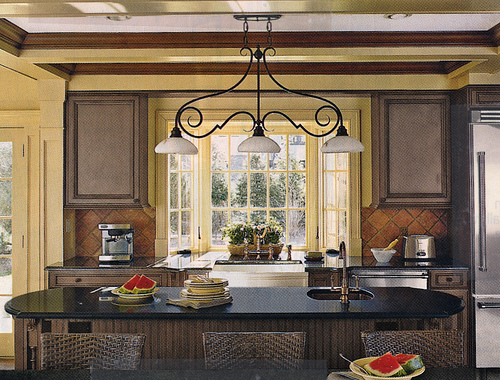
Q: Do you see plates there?
A: Yes, there is a plate.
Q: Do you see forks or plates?
A: Yes, there is a plate.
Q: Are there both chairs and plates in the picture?
A: Yes, there are both a plate and a chair.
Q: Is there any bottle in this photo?
A: No, there are no bottles.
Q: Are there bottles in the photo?
A: No, there are no bottles.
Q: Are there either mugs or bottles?
A: No, there are no bottles or mugs.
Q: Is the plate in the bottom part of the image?
A: Yes, the plate is in the bottom of the image.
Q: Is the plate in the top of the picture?
A: No, the plate is in the bottom of the image.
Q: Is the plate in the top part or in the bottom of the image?
A: The plate is in the bottom of the image.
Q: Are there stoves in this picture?
A: No, there are no stoves.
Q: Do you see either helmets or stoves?
A: No, there are no stoves or helmets.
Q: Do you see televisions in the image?
A: No, there are no televisions.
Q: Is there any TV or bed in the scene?
A: No, there are no televisions or beds.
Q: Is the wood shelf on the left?
A: Yes, the shelf is on the left of the image.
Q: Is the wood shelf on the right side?
A: No, the shelf is on the left of the image.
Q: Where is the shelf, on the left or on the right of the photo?
A: The shelf is on the left of the image.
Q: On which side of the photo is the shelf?
A: The shelf is on the left of the image.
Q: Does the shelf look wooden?
A: Yes, the shelf is wooden.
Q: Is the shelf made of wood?
A: Yes, the shelf is made of wood.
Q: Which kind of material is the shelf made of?
A: The shelf is made of wood.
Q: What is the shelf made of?
A: The shelf is made of wood.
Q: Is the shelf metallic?
A: No, the shelf is wooden.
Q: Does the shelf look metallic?
A: No, the shelf is wooden.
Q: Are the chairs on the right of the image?
A: Yes, the chairs are on the right of the image.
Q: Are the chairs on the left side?
A: No, the chairs are on the right of the image.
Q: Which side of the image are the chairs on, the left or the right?
A: The chairs are on the right of the image.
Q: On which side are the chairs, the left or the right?
A: The chairs are on the right of the image.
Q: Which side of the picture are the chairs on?
A: The chairs are on the right of the image.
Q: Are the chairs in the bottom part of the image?
A: Yes, the chairs are in the bottom of the image.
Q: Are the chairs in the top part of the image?
A: No, the chairs are in the bottom of the image.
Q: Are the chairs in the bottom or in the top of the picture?
A: The chairs are in the bottom of the image.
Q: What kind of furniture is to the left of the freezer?
A: The pieces of furniture are chairs.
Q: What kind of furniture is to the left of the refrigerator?
A: The pieces of furniture are chairs.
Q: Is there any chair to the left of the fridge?
A: Yes, there are chairs to the left of the fridge.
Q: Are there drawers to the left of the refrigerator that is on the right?
A: No, there are chairs to the left of the refrigerator.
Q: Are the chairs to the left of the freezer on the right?
A: Yes, the chairs are to the left of the fridge.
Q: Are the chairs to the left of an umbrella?
A: No, the chairs are to the left of the fridge.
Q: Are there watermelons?
A: Yes, there is a watermelon.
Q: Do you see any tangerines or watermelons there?
A: Yes, there is a watermelon.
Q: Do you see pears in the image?
A: No, there are no pears.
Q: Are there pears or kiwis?
A: No, there are no pears or kiwis.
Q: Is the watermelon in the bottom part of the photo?
A: Yes, the watermelon is in the bottom of the image.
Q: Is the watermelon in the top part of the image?
A: No, the watermelon is in the bottom of the image.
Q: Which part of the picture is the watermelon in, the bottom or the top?
A: The watermelon is in the bottom of the image.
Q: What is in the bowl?
A: The watermelon is in the bowl.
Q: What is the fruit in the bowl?
A: The fruit is a watermelon.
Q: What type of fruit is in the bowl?
A: The fruit is a watermelon.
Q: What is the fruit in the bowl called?
A: The fruit is a watermelon.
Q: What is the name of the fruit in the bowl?
A: The fruit is a watermelon.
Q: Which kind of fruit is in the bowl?
A: The fruit is a watermelon.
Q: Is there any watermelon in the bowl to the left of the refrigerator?
A: Yes, there is a watermelon in the bowl.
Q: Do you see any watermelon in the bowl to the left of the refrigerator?
A: Yes, there is a watermelon in the bowl.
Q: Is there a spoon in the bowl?
A: No, there is a watermelon in the bowl.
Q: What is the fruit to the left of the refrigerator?
A: The fruit is a watermelon.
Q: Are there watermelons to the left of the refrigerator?
A: Yes, there is a watermelon to the left of the refrigerator.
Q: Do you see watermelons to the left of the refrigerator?
A: Yes, there is a watermelon to the left of the refrigerator.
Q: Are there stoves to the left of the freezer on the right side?
A: No, there is a watermelon to the left of the refrigerator.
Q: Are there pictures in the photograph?
A: No, there are no pictures.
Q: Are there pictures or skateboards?
A: No, there are no pictures or skateboards.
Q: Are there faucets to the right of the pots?
A: Yes, there is a faucet to the right of the pots.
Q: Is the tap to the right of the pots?
A: Yes, the tap is to the right of the pots.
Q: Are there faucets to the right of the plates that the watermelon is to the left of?
A: Yes, there is a faucet to the right of the plates.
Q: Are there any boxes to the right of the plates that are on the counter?
A: No, there is a faucet to the right of the plates.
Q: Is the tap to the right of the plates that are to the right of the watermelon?
A: Yes, the tap is to the right of the plates.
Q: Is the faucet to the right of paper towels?
A: No, the faucet is to the right of the plates.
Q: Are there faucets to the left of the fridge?
A: Yes, there is a faucet to the left of the fridge.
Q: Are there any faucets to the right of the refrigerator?
A: No, the faucet is to the left of the refrigerator.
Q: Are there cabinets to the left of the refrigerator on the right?
A: No, there is a faucet to the left of the freezer.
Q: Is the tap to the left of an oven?
A: No, the tap is to the left of the freezer.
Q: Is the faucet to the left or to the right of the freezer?
A: The faucet is to the left of the freezer.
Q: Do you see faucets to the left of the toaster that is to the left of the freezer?
A: Yes, there is a faucet to the left of the toaster.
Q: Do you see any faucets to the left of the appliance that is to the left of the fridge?
A: Yes, there is a faucet to the left of the toaster.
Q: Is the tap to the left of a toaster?
A: Yes, the tap is to the left of a toaster.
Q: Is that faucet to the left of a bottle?
A: No, the faucet is to the left of a toaster.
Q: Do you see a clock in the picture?
A: No, there are no clocks.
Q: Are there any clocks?
A: No, there are no clocks.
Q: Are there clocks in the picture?
A: No, there are no clocks.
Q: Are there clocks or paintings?
A: No, there are no clocks or paintings.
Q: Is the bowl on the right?
A: Yes, the bowl is on the right of the image.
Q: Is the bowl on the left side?
A: No, the bowl is on the right of the image.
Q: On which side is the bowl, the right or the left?
A: The bowl is on the right of the image.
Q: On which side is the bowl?
A: The bowl is on the right of the image.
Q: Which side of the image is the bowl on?
A: The bowl is on the right of the image.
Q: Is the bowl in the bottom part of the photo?
A: Yes, the bowl is in the bottom of the image.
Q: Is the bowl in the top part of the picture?
A: No, the bowl is in the bottom of the image.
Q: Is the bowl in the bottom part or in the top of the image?
A: The bowl is in the bottom of the image.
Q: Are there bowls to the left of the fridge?
A: Yes, there is a bowl to the left of the fridge.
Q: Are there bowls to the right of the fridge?
A: No, the bowl is to the left of the fridge.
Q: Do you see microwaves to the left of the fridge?
A: No, there is a bowl to the left of the fridge.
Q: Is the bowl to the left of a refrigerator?
A: Yes, the bowl is to the left of a refrigerator.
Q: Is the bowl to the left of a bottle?
A: No, the bowl is to the left of a refrigerator.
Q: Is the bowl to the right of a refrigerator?
A: No, the bowl is to the left of a refrigerator.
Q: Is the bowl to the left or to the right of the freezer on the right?
A: The bowl is to the left of the freezer.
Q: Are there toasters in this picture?
A: Yes, there is a toaster.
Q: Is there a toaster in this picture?
A: Yes, there is a toaster.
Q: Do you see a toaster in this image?
A: Yes, there is a toaster.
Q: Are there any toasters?
A: Yes, there is a toaster.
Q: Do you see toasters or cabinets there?
A: Yes, there is a toaster.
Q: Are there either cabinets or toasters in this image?
A: Yes, there is a toaster.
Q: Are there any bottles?
A: No, there are no bottles.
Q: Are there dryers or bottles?
A: No, there are no bottles or dryers.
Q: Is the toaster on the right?
A: Yes, the toaster is on the right of the image.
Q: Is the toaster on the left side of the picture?
A: No, the toaster is on the right of the image.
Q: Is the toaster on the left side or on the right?
A: The toaster is on the right of the image.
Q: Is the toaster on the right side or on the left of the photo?
A: The toaster is on the right of the image.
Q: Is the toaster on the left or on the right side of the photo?
A: The toaster is on the right of the image.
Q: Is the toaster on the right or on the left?
A: The toaster is on the right of the image.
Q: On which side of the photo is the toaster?
A: The toaster is on the right of the image.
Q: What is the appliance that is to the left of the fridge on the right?
A: The appliance is a toaster.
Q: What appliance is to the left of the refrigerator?
A: The appliance is a toaster.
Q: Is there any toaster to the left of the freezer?
A: Yes, there is a toaster to the left of the freezer.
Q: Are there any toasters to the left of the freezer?
A: Yes, there is a toaster to the left of the freezer.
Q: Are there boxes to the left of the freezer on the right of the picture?
A: No, there is a toaster to the left of the fridge.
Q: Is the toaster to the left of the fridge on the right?
A: Yes, the toaster is to the left of the freezer.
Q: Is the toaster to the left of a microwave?
A: No, the toaster is to the left of the freezer.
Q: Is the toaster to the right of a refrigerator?
A: No, the toaster is to the left of a refrigerator.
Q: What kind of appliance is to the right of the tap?
A: The appliance is a toaster.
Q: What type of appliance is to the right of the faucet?
A: The appliance is a toaster.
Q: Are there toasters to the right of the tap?
A: Yes, there is a toaster to the right of the tap.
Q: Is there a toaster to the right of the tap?
A: Yes, there is a toaster to the right of the tap.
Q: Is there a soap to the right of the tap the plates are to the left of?
A: No, there is a toaster to the right of the faucet.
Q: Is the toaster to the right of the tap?
A: Yes, the toaster is to the right of the tap.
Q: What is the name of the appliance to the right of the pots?
A: The appliance is a toaster.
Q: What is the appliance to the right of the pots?
A: The appliance is a toaster.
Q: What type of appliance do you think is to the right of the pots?
A: The appliance is a toaster.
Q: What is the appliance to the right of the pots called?
A: The appliance is a toaster.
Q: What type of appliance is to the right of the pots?
A: The appliance is a toaster.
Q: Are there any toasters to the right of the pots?
A: Yes, there is a toaster to the right of the pots.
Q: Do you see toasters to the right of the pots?
A: Yes, there is a toaster to the right of the pots.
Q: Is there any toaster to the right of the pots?
A: Yes, there is a toaster to the right of the pots.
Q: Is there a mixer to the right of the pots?
A: No, there is a toaster to the right of the pots.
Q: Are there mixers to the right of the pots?
A: No, there is a toaster to the right of the pots.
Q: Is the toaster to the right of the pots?
A: Yes, the toaster is to the right of the pots.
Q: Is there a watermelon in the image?
A: Yes, there is a watermelon.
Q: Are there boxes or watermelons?
A: Yes, there is a watermelon.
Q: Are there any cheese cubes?
A: No, there are no cheese cubes.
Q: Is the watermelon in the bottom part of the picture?
A: Yes, the watermelon is in the bottom of the image.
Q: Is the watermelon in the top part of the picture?
A: No, the watermelon is in the bottom of the image.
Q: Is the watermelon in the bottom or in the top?
A: The watermelon is in the bottom of the image.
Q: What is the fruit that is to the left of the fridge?
A: The fruit is a watermelon.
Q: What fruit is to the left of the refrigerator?
A: The fruit is a watermelon.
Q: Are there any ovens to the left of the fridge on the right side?
A: No, there is a watermelon to the left of the refrigerator.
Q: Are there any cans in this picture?
A: No, there are no cans.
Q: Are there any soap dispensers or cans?
A: No, there are no cans or soap dispensers.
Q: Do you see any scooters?
A: No, there are no scooters.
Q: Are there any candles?
A: No, there are no candles.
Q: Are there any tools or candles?
A: No, there are no candles or tools.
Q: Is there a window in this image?
A: Yes, there is a window.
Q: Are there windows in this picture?
A: Yes, there is a window.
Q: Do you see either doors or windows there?
A: Yes, there is a window.